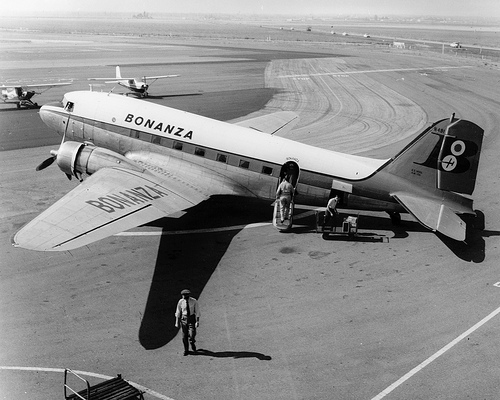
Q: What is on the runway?
A: A large plane is on the runway.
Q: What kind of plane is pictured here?
A: A picture of an older plane.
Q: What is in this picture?
A: The tail of an airplane.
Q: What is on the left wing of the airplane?
A: The word BONANZA is written on the left wing of the airplane.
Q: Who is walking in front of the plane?
A: A man is walking in front of the plane.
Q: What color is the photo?
A: Black and white.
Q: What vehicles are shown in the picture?
A: Planes.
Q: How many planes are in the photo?
A: 3.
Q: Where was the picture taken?
A: Airfield.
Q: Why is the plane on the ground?
A: It has landed.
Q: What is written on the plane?
A: Bonanza.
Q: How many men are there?
A: 3.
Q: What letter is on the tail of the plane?
A: B.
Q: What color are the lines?
A: White.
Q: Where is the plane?
A: At a airport.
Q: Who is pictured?
A: Men.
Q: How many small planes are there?
A: 2.